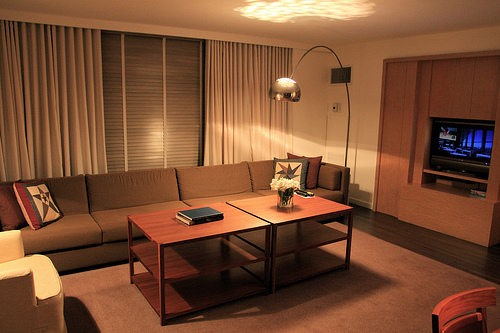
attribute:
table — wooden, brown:
[127, 192, 356, 325]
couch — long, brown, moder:
[0, 159, 350, 273]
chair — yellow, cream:
[0, 229, 69, 331]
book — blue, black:
[176, 206, 224, 227]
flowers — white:
[269, 174, 296, 193]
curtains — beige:
[206, 39, 293, 166]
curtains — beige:
[0, 23, 110, 186]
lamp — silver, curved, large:
[270, 46, 353, 169]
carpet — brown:
[61, 221, 498, 332]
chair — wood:
[431, 287, 498, 332]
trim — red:
[16, 181, 39, 233]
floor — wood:
[332, 201, 500, 282]